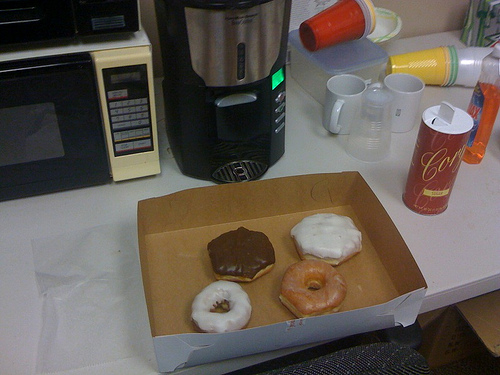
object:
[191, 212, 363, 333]
donuts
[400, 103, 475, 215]
canister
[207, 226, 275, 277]
chocolate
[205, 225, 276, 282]
donut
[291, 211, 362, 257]
icing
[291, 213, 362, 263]
donut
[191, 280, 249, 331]
vanilla frosting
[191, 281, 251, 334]
donut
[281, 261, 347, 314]
plain glazing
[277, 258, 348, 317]
donut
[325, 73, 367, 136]
mug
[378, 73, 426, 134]
mug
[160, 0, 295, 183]
coffee pot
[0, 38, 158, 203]
microwave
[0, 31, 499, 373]
counter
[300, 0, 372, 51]
plastic cup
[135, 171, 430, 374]
box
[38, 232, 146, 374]
wax paper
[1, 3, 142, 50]
microwave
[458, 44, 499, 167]
dish soap bottle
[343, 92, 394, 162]
plastic cups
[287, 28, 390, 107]
tupperware bowl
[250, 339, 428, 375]
fabric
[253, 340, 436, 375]
bench